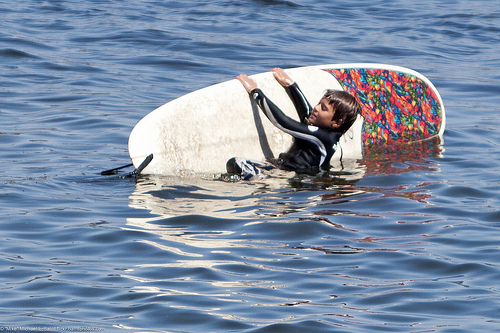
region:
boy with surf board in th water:
[126, 60, 447, 182]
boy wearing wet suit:
[222, 65, 357, 180]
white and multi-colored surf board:
[125, 60, 445, 180]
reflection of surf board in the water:
[116, 145, 446, 315]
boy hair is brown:
[305, 85, 360, 125]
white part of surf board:
[126, 61, 351, 171]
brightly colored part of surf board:
[325, 66, 440, 166]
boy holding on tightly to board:
[221, 65, 363, 186]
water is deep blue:
[2, 188, 497, 332]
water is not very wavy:
[3, 2, 495, 332]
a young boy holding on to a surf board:
[125, 62, 458, 201]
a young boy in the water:
[206, 59, 383, 222]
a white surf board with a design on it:
[127, 63, 446, 193]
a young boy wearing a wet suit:
[208, 74, 382, 196]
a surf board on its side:
[138, 63, 440, 192]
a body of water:
[22, 202, 469, 327]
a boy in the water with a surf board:
[101, 60, 442, 205]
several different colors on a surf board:
[356, 62, 439, 176]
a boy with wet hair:
[306, 101, 360, 148]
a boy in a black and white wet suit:
[226, 72, 358, 179]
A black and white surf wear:
[252, 85, 332, 178]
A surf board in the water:
[146, 99, 248, 166]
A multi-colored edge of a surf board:
[366, 59, 441, 148]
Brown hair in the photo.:
[332, 87, 357, 125]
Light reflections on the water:
[185, 200, 236, 257]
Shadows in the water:
[302, 169, 364, 214]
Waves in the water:
[76, 250, 299, 315]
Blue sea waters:
[133, 205, 357, 298]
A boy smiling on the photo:
[307, 105, 321, 122]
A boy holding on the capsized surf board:
[182, 72, 363, 182]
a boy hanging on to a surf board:
[133, 58, 448, 208]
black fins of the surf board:
[110, 148, 159, 189]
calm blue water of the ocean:
[86, 218, 407, 323]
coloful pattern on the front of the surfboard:
[342, 60, 445, 159]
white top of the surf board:
[170, 97, 257, 172]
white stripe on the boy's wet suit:
[247, 101, 326, 166]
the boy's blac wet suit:
[238, 125, 350, 177]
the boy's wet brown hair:
[328, 85, 365, 125]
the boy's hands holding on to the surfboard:
[211, 62, 311, 95]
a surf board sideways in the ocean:
[106, 57, 443, 159]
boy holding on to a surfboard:
[286, 91, 346, 190]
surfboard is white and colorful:
[186, 132, 236, 169]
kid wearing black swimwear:
[262, 95, 329, 162]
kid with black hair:
[330, 98, 356, 128]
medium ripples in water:
[378, 240, 431, 282]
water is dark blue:
[293, 263, 338, 290]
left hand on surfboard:
[233, 72, 274, 106]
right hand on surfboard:
[268, 68, 300, 91]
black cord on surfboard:
[91, 159, 163, 177]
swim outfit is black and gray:
[278, 149, 350, 169]